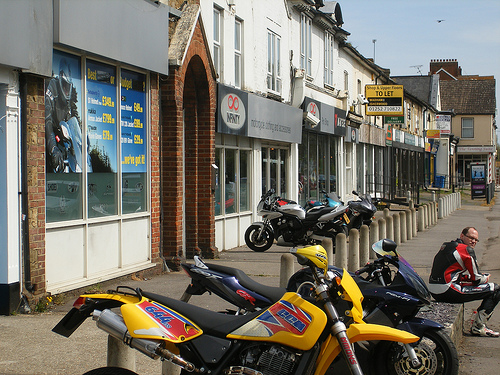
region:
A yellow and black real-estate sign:
[361, 80, 408, 120]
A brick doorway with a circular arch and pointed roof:
[166, 10, 220, 257]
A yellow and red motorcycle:
[82, 274, 407, 374]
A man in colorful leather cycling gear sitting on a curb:
[428, 222, 498, 342]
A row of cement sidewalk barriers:
[390, 193, 465, 230]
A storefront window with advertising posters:
[49, 54, 155, 223]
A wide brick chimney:
[427, 55, 462, 75]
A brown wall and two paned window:
[457, 115, 489, 144]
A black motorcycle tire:
[390, 319, 459, 372]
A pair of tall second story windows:
[296, 5, 346, 93]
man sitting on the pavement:
[431, 203, 496, 304]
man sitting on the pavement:
[405, 171, 495, 359]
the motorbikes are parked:
[228, 151, 404, 270]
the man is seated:
[437, 223, 498, 328]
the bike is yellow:
[85, 268, 415, 373]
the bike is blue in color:
[194, 249, 454, 333]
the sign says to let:
[365, 80, 403, 113]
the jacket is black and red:
[427, 235, 499, 279]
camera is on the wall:
[344, 90, 369, 112]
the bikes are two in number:
[81, 238, 441, 374]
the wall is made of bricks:
[171, 93, 222, 237]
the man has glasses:
[431, 220, 497, 337]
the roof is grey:
[447, 83, 480, 107]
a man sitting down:
[429, 228, 496, 339]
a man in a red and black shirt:
[432, 235, 498, 332]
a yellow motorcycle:
[66, 259, 392, 371]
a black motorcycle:
[212, 235, 452, 326]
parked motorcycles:
[56, 184, 493, 371]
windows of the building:
[45, 54, 152, 214]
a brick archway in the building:
[168, 54, 225, 249]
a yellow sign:
[363, 83, 405, 117]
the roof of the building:
[408, 68, 498, 114]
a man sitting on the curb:
[431, 235, 493, 319]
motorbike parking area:
[188, 175, 375, 357]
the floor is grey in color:
[18, 343, 70, 372]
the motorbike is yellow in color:
[200, 297, 372, 359]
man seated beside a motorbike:
[443, 209, 497, 326]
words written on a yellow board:
[371, 83, 416, 123]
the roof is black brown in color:
[452, 78, 492, 110]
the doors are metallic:
[73, 224, 139, 264]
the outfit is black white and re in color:
[431, 233, 493, 297]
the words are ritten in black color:
[370, 85, 404, 104]